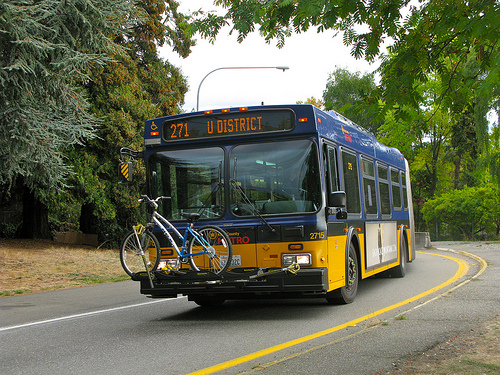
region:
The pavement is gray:
[101, 285, 274, 368]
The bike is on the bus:
[96, 193, 249, 288]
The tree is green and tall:
[32, 21, 148, 191]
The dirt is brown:
[3, 237, 103, 322]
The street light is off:
[222, 21, 310, 103]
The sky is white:
[216, 34, 301, 71]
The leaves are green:
[374, 59, 481, 132]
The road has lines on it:
[331, 263, 486, 361]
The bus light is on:
[254, 251, 325, 276]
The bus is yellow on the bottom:
[250, 243, 369, 334]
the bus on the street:
[131, 94, 393, 312]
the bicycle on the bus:
[95, 198, 236, 288]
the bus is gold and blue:
[101, 100, 392, 332]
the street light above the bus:
[188, 55, 305, 98]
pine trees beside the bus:
[7, 8, 95, 168]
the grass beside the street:
[13, 239, 129, 290]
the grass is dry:
[6, 234, 94, 287]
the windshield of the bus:
[233, 158, 319, 213]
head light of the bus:
[269, 242, 323, 273]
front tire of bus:
[323, 243, 365, 313]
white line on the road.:
[54, 306, 79, 328]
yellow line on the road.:
[243, 337, 271, 374]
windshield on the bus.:
[248, 153, 299, 200]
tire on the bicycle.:
[195, 233, 226, 266]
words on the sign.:
[204, 113, 266, 134]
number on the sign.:
[167, 123, 194, 137]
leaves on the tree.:
[450, 198, 476, 210]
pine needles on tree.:
[30, 113, 48, 132]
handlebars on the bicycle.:
[140, 190, 168, 208]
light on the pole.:
[268, 58, 293, 73]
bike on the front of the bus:
[121, 188, 226, 277]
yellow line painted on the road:
[219, 343, 316, 363]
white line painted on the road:
[19, 310, 70, 330]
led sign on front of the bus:
[169, 118, 267, 135]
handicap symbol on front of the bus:
[146, 119, 158, 134]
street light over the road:
[184, 45, 298, 102]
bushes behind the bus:
[425, 174, 494, 246]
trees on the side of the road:
[24, 18, 124, 245]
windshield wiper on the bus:
[228, 158, 282, 240]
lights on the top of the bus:
[199, 108, 251, 113]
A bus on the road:
[3, 98, 497, 371]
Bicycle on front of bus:
[116, 188, 261, 285]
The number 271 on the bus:
[163, 116, 193, 144]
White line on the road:
[1, 292, 187, 332]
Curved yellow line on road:
[185, 248, 470, 371]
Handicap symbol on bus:
[145, 117, 162, 135]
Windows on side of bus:
[357, 150, 410, 220]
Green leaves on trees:
[170, 0, 498, 239]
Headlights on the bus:
[153, 249, 315, 276]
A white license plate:
[214, 250, 245, 272]